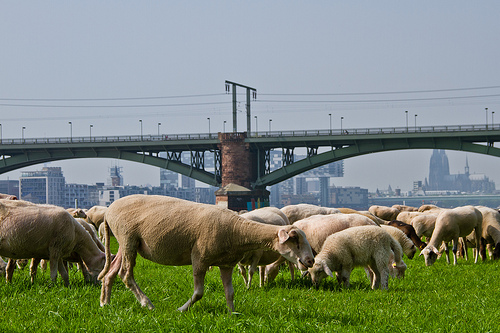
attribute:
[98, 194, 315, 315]
sheep — sheared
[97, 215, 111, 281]
tail — long, sheared, skinny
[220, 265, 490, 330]
field — green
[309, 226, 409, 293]
sheep — unsheared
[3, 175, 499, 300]
sheep — grazing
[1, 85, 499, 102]
power cable — overhead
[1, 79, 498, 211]
bridge — metal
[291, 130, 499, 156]
support — arched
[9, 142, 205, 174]
support — arched